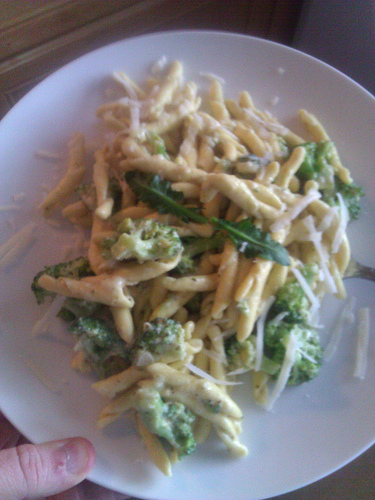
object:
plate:
[0, 31, 373, 499]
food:
[4, 56, 358, 478]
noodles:
[135, 92, 200, 139]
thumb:
[0, 440, 94, 499]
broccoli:
[143, 321, 182, 357]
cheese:
[19, 60, 355, 448]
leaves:
[210, 213, 293, 268]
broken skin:
[53, 456, 68, 475]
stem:
[143, 183, 205, 224]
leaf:
[127, 171, 205, 226]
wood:
[0, 1, 306, 453]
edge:
[268, 41, 373, 101]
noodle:
[39, 132, 86, 211]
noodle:
[301, 110, 353, 186]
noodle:
[37, 275, 135, 309]